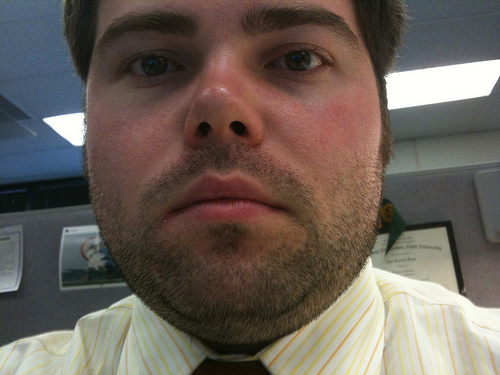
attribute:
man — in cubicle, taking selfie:
[59, 1, 408, 342]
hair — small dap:
[61, 1, 407, 88]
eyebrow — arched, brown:
[93, 10, 203, 52]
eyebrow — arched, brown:
[242, 9, 364, 55]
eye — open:
[120, 49, 187, 80]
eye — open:
[265, 45, 324, 75]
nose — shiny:
[184, 47, 264, 140]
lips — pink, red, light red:
[177, 170, 281, 220]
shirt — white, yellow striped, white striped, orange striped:
[0, 258, 499, 374]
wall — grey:
[2, 153, 497, 346]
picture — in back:
[58, 225, 127, 290]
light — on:
[42, 106, 96, 150]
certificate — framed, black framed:
[361, 220, 462, 296]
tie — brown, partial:
[190, 353, 267, 374]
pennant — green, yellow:
[377, 196, 404, 254]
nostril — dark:
[195, 118, 215, 141]